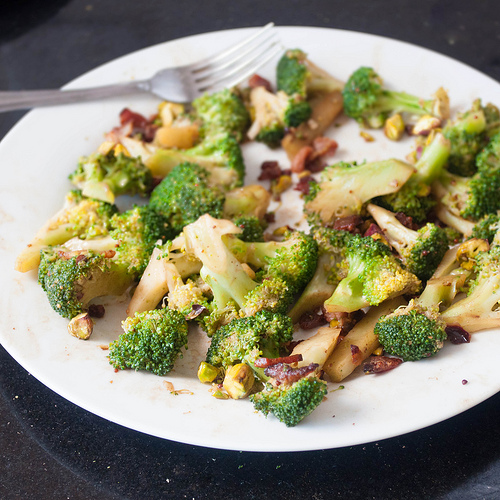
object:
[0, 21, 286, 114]
fork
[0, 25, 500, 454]
plate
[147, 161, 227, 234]
broccoli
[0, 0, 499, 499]
table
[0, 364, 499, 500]
reflection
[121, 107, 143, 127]
pepper